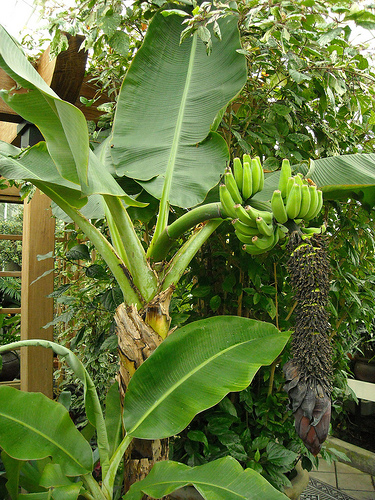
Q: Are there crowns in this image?
A: No, there are no crowns.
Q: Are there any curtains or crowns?
A: No, there are no crowns or curtains.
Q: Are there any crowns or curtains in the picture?
A: No, there are no crowns or curtains.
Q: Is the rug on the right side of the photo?
A: Yes, the rug is on the right of the image.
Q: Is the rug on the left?
A: No, the rug is on the right of the image.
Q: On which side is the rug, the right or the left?
A: The rug is on the right of the image.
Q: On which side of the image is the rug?
A: The rug is on the right of the image.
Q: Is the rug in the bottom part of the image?
A: Yes, the rug is in the bottom of the image.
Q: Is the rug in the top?
A: No, the rug is in the bottom of the image.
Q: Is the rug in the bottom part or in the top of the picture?
A: The rug is in the bottom of the image.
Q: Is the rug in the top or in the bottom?
A: The rug is in the bottom of the image.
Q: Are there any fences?
A: No, there are no fences.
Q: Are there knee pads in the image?
A: No, there are no knee pads.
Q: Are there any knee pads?
A: No, there are no knee pads.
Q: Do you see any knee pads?
A: No, there are no knee pads.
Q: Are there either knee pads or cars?
A: No, there are no knee pads or cars.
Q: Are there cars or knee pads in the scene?
A: No, there are no knee pads or cars.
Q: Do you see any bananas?
A: Yes, there are bananas.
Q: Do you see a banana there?
A: Yes, there are bananas.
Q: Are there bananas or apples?
A: Yes, there are bananas.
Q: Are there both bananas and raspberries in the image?
A: No, there are bananas but no raspberries.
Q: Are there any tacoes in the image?
A: No, there are no tacoes.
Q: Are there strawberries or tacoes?
A: No, there are no tacoes or strawberries.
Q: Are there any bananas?
A: Yes, there is a banana.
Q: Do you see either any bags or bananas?
A: Yes, there is a banana.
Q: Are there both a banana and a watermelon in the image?
A: No, there is a banana but no watermelons.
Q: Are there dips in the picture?
A: No, there are no dips.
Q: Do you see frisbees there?
A: No, there are no frisbees.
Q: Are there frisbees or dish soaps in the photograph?
A: No, there are no frisbees or dish soaps.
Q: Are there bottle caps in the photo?
A: No, there are no bottle caps.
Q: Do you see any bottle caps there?
A: No, there are no bottle caps.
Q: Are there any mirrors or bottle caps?
A: No, there are no bottle caps or mirrors.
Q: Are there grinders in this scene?
A: No, there are no grinders.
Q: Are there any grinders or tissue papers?
A: No, there are no grinders or tissue papers.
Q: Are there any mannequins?
A: No, there are no mannequins.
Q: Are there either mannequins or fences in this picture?
A: No, there are no mannequins or fences.